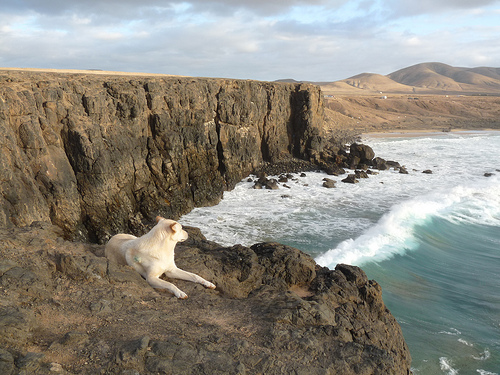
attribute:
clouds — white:
[183, 29, 322, 58]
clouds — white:
[307, 48, 397, 68]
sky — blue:
[5, 0, 498, 80]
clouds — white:
[197, 4, 279, 24]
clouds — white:
[234, 22, 375, 65]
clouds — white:
[274, 25, 334, 67]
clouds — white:
[141, 27, 240, 77]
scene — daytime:
[10, 1, 499, 372]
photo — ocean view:
[5, 4, 493, 373]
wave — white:
[324, 175, 462, 280]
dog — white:
[107, 213, 216, 305]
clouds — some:
[173, 24, 350, 60]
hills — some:
[330, 51, 499, 101]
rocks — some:
[265, 141, 413, 186]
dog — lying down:
[81, 199, 242, 319]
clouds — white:
[6, 13, 467, 85]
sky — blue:
[0, 2, 492, 67]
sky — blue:
[4, 6, 498, 86]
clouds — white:
[0, 10, 490, 84]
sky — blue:
[0, 8, 494, 78]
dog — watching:
[101, 202, 228, 305]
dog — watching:
[82, 199, 236, 308]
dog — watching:
[90, 202, 244, 314]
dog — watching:
[90, 186, 226, 316]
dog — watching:
[93, 206, 238, 320]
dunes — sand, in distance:
[317, 42, 486, 111]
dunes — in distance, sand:
[328, 44, 498, 98]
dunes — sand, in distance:
[301, 55, 495, 105]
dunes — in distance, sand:
[301, 55, 499, 96]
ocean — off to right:
[157, 119, 497, 373]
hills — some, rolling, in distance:
[297, 48, 493, 100]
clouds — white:
[1, 2, 497, 78]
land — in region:
[301, 73, 482, 122]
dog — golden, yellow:
[90, 204, 226, 314]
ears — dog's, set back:
[144, 202, 191, 247]